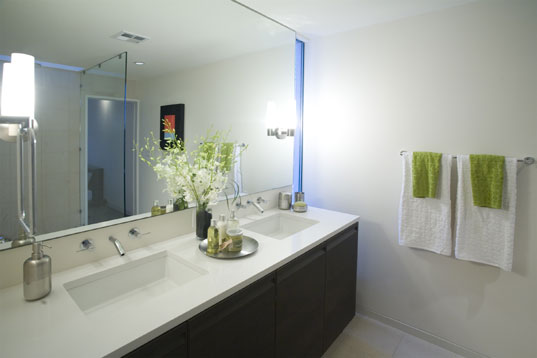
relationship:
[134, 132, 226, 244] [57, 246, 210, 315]
flower arrangement on sink